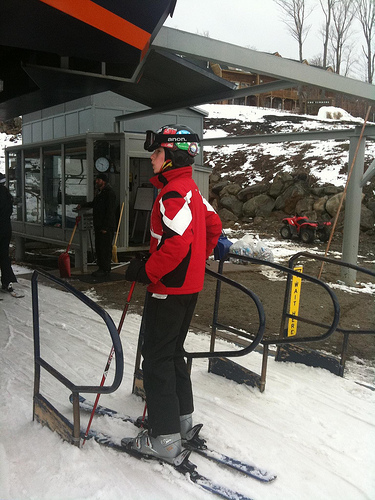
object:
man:
[121, 123, 222, 462]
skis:
[65, 394, 278, 481]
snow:
[0, 277, 374, 500]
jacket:
[141, 162, 223, 296]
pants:
[140, 291, 198, 438]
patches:
[145, 190, 194, 284]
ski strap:
[134, 438, 152, 448]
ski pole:
[77, 257, 147, 452]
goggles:
[142, 127, 202, 152]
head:
[144, 120, 202, 180]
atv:
[280, 212, 330, 241]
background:
[2, 3, 374, 311]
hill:
[203, 94, 370, 258]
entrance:
[31, 253, 252, 437]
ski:
[75, 420, 248, 500]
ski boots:
[120, 423, 182, 462]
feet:
[119, 431, 183, 462]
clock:
[95, 155, 109, 173]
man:
[73, 172, 119, 278]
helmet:
[147, 121, 199, 165]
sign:
[287, 266, 304, 340]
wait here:
[291, 273, 299, 334]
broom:
[110, 201, 125, 264]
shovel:
[56, 215, 81, 277]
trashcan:
[213, 233, 232, 263]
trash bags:
[228, 239, 274, 267]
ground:
[0, 227, 374, 500]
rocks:
[241, 195, 276, 217]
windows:
[63, 143, 86, 230]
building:
[8, 86, 209, 272]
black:
[95, 189, 113, 269]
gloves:
[125, 260, 150, 283]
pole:
[340, 139, 365, 284]